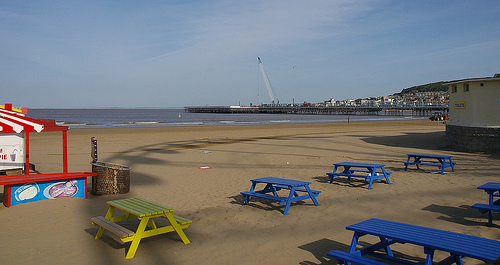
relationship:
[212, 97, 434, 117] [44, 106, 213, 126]
pier above water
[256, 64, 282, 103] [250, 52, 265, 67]
white smoke behind jet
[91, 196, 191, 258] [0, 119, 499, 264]
bench at beach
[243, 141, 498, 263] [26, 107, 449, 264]
benches on beach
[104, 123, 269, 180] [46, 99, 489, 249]
shadow on sand